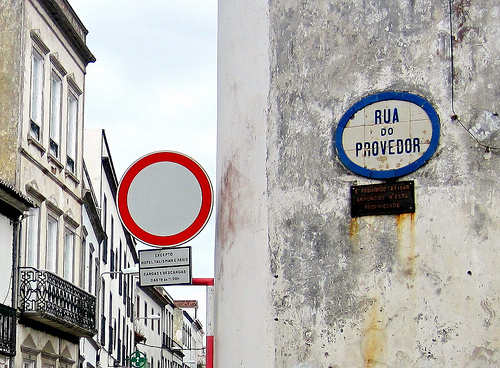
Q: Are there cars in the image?
A: No, there are no cars.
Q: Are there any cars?
A: No, there are no cars.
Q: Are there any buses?
A: No, there are no buses.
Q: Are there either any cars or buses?
A: No, there are no buses or cars.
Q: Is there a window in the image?
A: Yes, there is a window.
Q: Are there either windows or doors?
A: Yes, there is a window.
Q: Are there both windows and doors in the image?
A: No, there is a window but no doors.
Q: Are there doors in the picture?
A: No, there are no doors.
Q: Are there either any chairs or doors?
A: No, there are no doors or chairs.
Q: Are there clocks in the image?
A: No, there are no clocks.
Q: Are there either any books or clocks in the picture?
A: No, there are no clocks or books.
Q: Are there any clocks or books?
A: No, there are no clocks or books.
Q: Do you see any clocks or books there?
A: No, there are no clocks or books.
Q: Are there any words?
A: Yes, there are words.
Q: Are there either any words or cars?
A: Yes, there are words.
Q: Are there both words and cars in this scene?
A: No, there are words but no cars.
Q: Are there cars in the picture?
A: No, there are no cars.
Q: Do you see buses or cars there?
A: No, there are no cars or buses.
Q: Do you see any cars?
A: No, there are no cars.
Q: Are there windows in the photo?
A: Yes, there is a window.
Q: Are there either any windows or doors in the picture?
A: Yes, there is a window.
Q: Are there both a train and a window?
A: No, there is a window but no trains.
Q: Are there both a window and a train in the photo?
A: No, there is a window but no trains.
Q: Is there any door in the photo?
A: No, there are no doors.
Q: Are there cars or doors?
A: No, there are no doors or cars.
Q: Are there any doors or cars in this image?
A: No, there are no doors or cars.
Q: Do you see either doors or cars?
A: No, there are no doors or cars.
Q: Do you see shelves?
A: No, there are no shelves.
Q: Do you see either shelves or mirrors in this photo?
A: No, there are no shelves or mirrors.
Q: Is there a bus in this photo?
A: No, there are no buses.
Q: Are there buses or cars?
A: No, there are no buses or cars.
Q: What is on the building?
A: The sign is on the building.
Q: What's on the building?
A: The sign is on the building.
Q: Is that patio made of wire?
A: Yes, the patio is made of wire.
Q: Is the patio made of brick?
A: No, the patio is made of wire.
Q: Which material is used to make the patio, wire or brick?
A: The patio is made of wire.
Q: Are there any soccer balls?
A: No, there are no soccer balls.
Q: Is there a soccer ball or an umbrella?
A: No, there are no soccer balls or umbrellas.